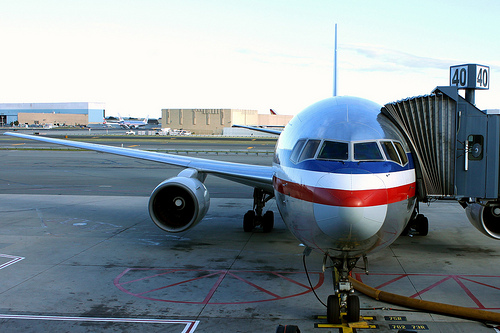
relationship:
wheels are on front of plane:
[325, 294, 361, 324] [2, 20, 429, 324]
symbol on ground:
[113, 265, 326, 305] [1, 160, 500, 331]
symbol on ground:
[356, 271, 500, 312] [1, 160, 500, 331]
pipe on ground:
[343, 271, 500, 325] [1, 160, 500, 331]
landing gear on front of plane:
[326, 251, 365, 322] [2, 20, 429, 324]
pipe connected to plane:
[343, 271, 500, 325] [2, 20, 429, 324]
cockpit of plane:
[292, 123, 415, 167] [2, 20, 429, 324]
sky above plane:
[3, 0, 499, 118] [2, 20, 429, 324]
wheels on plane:
[325, 294, 361, 324] [2, 20, 429, 324]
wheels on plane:
[242, 209, 277, 234] [2, 20, 429, 324]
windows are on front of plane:
[289, 140, 408, 164] [2, 20, 429, 324]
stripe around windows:
[269, 148, 417, 175] [289, 140, 408, 164]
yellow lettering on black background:
[390, 315, 403, 321] [383, 315, 409, 321]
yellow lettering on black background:
[391, 324, 425, 330] [389, 322, 430, 331]